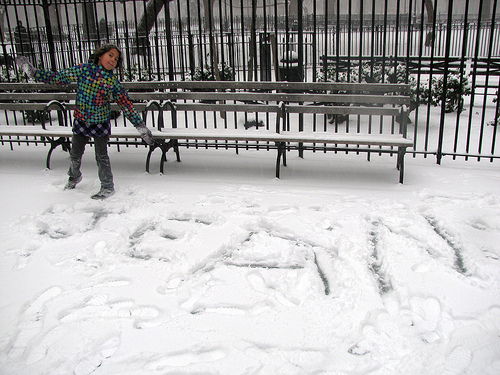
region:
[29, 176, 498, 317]
JEAN written on snow.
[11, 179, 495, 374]
Snow has been trampled on.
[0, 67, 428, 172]
Bench seats covered in snow.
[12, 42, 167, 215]
Girl playing in snow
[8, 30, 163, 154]
Girl is wearing mittens.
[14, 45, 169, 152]
Mittens are covered with snow.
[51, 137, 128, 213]
Girl is wearing boots.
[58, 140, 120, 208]
Boots are covered in snow.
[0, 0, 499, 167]
Black fence behind benches.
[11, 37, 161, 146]
Multi colored jacket with hood.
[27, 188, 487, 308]
JEAN is written in snow.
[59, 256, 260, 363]
ground is white in color.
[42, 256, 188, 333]
snow is in ground.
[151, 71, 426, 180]
bench in black in color.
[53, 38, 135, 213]
girl is standing near the bench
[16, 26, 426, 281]
day time picture.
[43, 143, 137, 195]
girl is wearing grey color pant.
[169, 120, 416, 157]
bench is covered with snow.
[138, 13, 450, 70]
fence is black in color.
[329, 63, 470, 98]
plants are covered with snow.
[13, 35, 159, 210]
girl playing in snow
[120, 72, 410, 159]
bench is covered snow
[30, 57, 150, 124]
girl has a colorful coat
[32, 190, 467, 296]
name spelled in snow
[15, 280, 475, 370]
snow is bright white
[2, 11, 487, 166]
iron fence behind bench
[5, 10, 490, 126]
iron fence is black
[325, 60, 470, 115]
shrubs with snow on them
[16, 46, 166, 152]
girl has gray gloves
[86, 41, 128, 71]
girl has brown hair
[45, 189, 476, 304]
Jean left her mark.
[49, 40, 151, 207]
Maybe this is Jean.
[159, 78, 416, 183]
Snow wooden park bench.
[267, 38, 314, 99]
Park trash barrel needed.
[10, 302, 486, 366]
Many footprints done walkway.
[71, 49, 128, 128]
Wearing many colored jacket.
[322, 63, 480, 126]
Green bushes covered snow.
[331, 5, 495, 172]
Metal fencing back bench.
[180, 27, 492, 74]
Lake shows beyond park.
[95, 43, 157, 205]
Mittens and boots winter garb.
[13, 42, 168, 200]
girl playing in the snow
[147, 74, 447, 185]
park bench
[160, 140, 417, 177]
legs on the park bench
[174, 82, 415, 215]
park bench on snowy park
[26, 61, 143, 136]
colorful jacket on little girl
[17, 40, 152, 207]
little girl wearing jeans and gloves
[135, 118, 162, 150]
gloves on little girls hand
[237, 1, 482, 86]
wire fence in park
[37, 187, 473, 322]
name written on snow